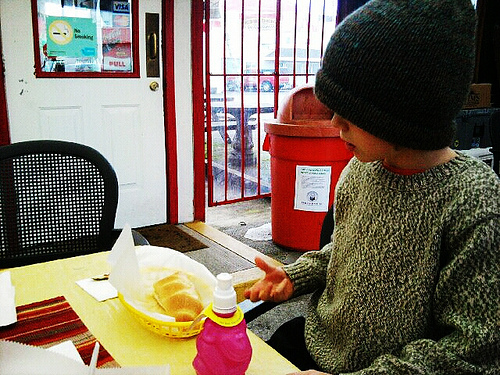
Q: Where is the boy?
A: In a restaurant.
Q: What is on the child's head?
A: A knit hat.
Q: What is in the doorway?
A: A red metal gate.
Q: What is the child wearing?
A: A thick grey sweater.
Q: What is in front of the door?
A: A red garbage can.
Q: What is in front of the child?
A: A table.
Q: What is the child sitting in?
A: A chair.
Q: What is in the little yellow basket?
A: A sandwich.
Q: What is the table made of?
A: Light wood.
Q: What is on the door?
A: A window.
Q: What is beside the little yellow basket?
A: A drink bottle.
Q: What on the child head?
A: Wool hat.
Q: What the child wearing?
A: Wool sweater.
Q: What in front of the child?
A: Table.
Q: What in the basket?
A: Sandwich.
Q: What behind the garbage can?
A: Bars.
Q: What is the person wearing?
A: A hat.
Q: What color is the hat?
A: Black.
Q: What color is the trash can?
A: Red.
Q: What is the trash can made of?
A: Plastic.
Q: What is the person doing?
A: Eating.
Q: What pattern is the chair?
A: Mesh.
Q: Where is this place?
A: Restaurant.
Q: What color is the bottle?
A: Pink.